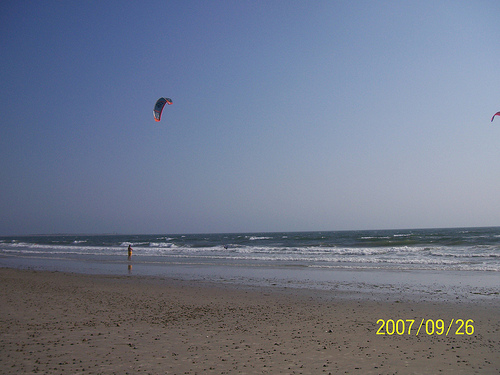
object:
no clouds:
[218, 50, 374, 180]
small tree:
[269, 105, 448, 214]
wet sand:
[189, 242, 323, 340]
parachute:
[489, 109, 498, 124]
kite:
[152, 96, 173, 122]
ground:
[267, 280, 499, 374]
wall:
[257, 108, 297, 150]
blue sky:
[0, 0, 499, 230]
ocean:
[1, 225, 500, 269]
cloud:
[0, 0, 499, 205]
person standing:
[125, 244, 133, 258]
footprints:
[0, 299, 499, 373]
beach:
[0, 243, 499, 372]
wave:
[0, 226, 500, 258]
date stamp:
[375, 317, 475, 337]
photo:
[1, 0, 498, 374]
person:
[127, 243, 133, 256]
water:
[0, 228, 498, 299]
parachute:
[149, 96, 173, 122]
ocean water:
[1, 227, 500, 311]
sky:
[0, 0, 499, 228]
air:
[1, 0, 499, 191]